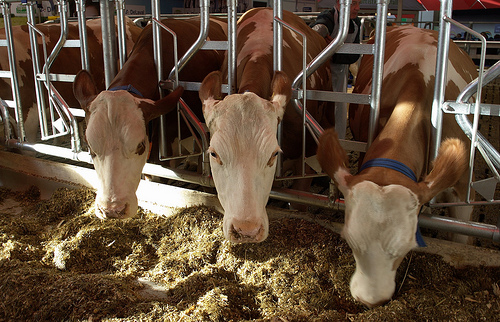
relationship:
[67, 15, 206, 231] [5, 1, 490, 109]
cow behind fence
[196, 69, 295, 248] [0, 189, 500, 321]
cow eating grass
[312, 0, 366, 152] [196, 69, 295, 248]
farmer behind cow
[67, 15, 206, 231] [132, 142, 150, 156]
cow has eye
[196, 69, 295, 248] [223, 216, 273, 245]
cow has nose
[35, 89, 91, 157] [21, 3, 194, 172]
light on gate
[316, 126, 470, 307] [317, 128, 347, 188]
cow has ear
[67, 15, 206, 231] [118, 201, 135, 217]
cow has nostril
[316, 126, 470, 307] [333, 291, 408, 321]
cow grazing on grass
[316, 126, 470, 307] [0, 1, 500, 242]
cow in a fence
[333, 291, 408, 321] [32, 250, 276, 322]
grass on floor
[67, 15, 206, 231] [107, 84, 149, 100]
cow has collar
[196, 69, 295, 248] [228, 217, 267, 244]
cow has nostrils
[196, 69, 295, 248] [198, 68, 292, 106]
cow has ears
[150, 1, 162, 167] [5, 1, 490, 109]
spoke in fence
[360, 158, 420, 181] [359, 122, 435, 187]
collar around neck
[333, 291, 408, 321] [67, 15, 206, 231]
grass eaten by a cow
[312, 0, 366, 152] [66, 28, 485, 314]
man behind cows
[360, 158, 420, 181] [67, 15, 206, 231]
collar on a cow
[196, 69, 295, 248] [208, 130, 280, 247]
cow has face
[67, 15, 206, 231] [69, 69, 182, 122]
cow has ears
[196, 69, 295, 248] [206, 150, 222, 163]
cow has eye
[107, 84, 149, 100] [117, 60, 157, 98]
collar around neck